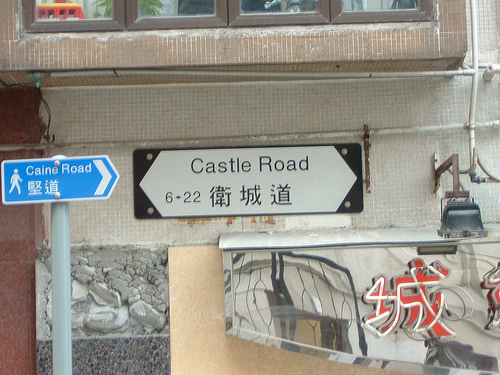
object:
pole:
[49, 201, 72, 375]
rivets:
[54, 160, 61, 199]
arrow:
[93, 159, 113, 195]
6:
[165, 190, 174, 203]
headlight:
[437, 197, 488, 238]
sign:
[132, 142, 365, 219]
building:
[0, 0, 500, 375]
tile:
[375, 85, 405, 106]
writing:
[27, 179, 59, 197]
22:
[183, 190, 202, 203]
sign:
[0, 154, 122, 207]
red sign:
[361, 256, 453, 337]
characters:
[209, 183, 292, 208]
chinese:
[360, 257, 466, 340]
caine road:
[25, 162, 92, 176]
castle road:
[191, 155, 309, 173]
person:
[7, 168, 24, 194]